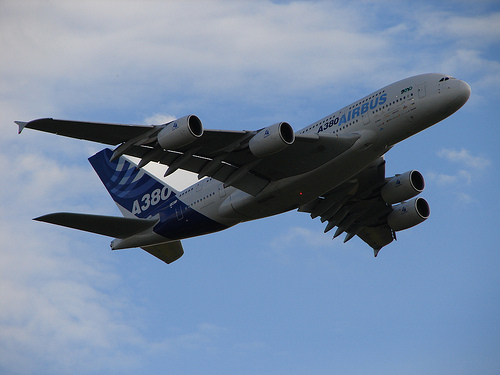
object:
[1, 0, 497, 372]
blue sky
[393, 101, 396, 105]
windows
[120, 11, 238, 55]
clouds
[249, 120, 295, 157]
engine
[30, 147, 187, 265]
tail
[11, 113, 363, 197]
wing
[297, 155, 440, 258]
wing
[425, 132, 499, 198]
ground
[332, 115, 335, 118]
windows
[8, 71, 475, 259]
plane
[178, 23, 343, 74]
clouds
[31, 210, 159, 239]
edge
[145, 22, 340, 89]
clouds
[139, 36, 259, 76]
clouds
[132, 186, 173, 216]
a380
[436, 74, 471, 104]
nose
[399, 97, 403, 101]
window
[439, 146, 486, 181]
clouds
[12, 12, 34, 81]
clouds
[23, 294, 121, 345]
clouds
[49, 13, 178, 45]
clouds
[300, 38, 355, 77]
clouds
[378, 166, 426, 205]
engine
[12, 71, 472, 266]
airliner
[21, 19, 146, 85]
white clouds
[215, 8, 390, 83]
white clouds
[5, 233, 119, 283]
white clouds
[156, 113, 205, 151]
engine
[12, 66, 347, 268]
side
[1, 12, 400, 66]
clouds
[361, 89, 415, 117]
row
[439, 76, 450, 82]
windows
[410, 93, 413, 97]
window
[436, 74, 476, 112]
tip